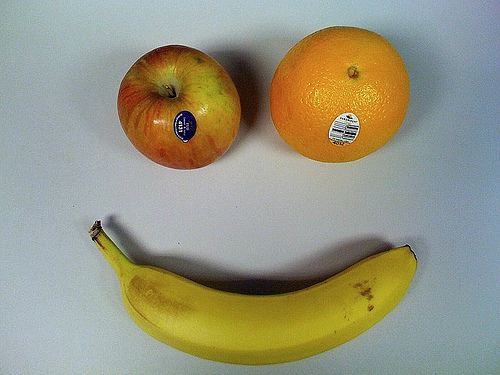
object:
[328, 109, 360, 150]
sticker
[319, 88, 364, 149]
rind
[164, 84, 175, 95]
brown stem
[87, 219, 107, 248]
brown stem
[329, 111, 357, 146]
sticker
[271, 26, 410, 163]
fruit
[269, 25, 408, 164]
orange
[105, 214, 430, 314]
shadow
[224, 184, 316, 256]
surface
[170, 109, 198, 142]
sticker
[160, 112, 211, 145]
sticker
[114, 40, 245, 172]
red apple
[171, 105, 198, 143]
sticker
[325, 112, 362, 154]
sticker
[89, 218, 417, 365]
banana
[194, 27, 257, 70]
shadows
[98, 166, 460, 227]
table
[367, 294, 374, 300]
bruises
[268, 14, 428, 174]
orange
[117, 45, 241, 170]
apple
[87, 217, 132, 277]
stem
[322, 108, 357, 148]
sticker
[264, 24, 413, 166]
orange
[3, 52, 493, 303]
photo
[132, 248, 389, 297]
shadow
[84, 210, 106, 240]
stem